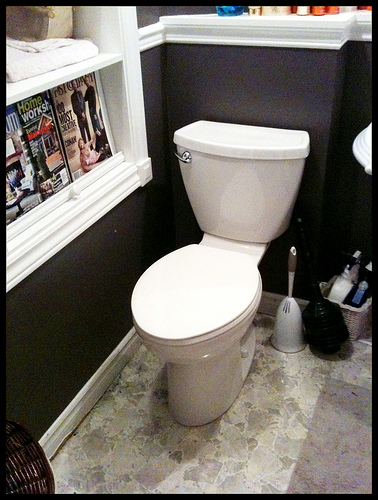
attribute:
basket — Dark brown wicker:
[2, 414, 54, 493]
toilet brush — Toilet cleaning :
[282, 243, 299, 294]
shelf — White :
[8, 14, 155, 287]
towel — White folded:
[3, 35, 100, 89]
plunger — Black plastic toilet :
[290, 203, 352, 365]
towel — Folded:
[5, 36, 99, 81]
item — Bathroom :
[213, 4, 243, 16]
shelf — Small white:
[165, 10, 374, 48]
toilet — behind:
[131, 118, 311, 426]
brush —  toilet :
[270, 242, 309, 357]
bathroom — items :
[316, 240, 374, 342]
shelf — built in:
[2, 18, 156, 201]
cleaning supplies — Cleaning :
[314, 241, 376, 311]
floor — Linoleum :
[50, 308, 374, 498]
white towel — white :
[1, 35, 99, 83]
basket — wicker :
[321, 265, 366, 341]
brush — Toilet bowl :
[275, 245, 303, 352]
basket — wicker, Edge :
[10, 423, 67, 494]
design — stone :
[273, 388, 363, 442]